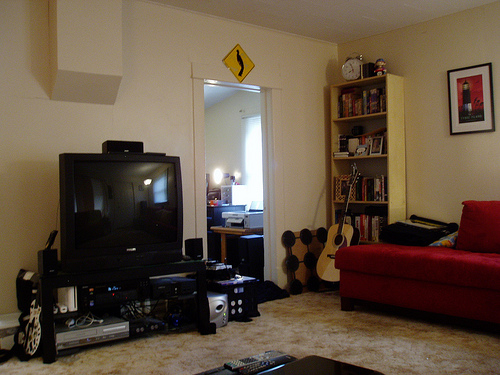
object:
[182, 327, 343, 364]
ground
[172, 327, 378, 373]
ground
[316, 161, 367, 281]
guitar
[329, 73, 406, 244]
bookshelf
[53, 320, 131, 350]
set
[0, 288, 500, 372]
carpet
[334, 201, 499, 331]
couch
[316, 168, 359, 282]
guitar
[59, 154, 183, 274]
television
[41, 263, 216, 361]
black on stand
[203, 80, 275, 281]
above the door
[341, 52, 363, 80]
clock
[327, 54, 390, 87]
top of bookshelf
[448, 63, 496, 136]
picture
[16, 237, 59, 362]
electric guitar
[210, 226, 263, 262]
table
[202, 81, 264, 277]
kitchen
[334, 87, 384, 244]
books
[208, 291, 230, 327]
stereo speaker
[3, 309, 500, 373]
ground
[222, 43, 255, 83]
sign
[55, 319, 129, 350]
dvd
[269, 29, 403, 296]
corner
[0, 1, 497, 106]
corner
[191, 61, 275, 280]
between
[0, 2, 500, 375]
room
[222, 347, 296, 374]
remote control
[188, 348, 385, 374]
table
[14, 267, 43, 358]
black and white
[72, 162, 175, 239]
screen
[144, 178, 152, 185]
light reflecting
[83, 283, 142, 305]
black cable box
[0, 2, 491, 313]
white wall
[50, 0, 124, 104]
inset